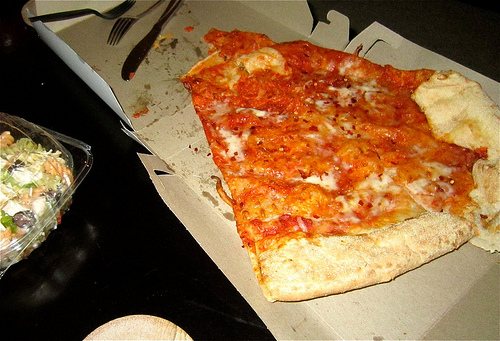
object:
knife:
[120, 0, 184, 82]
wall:
[93, 251, 148, 292]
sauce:
[249, 78, 293, 105]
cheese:
[181, 26, 487, 251]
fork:
[106, 0, 167, 48]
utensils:
[27, 0, 136, 26]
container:
[0, 110, 91, 279]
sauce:
[249, 141, 309, 164]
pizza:
[179, 28, 500, 302]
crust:
[434, 85, 485, 126]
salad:
[0, 130, 72, 270]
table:
[0, 0, 499, 340]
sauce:
[264, 188, 317, 215]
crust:
[299, 243, 382, 279]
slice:
[178, 27, 498, 301]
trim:
[31, 25, 111, 87]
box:
[20, 0, 497, 340]